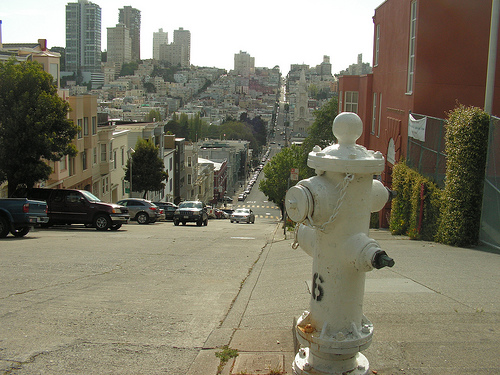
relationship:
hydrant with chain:
[278, 113, 400, 369] [308, 174, 354, 232]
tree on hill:
[5, 57, 75, 184] [50, 171, 479, 366]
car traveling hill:
[172, 200, 209, 226] [1, 215, 498, 372]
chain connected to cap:
[305, 171, 354, 227] [282, 184, 313, 224]